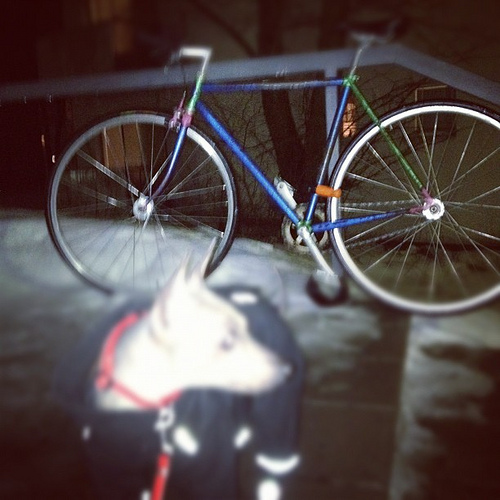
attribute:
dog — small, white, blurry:
[59, 236, 304, 499]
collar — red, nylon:
[93, 311, 184, 410]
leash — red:
[151, 409, 176, 500]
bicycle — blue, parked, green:
[44, 13, 500, 319]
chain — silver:
[279, 197, 445, 257]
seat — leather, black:
[338, 14, 409, 47]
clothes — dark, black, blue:
[52, 282, 300, 500]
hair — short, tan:
[95, 237, 295, 414]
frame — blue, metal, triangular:
[142, 43, 434, 236]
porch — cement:
[2, 295, 412, 499]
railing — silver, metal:
[1, 41, 500, 282]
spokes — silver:
[55, 123, 228, 283]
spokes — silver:
[338, 112, 499, 303]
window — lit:
[102, 118, 145, 167]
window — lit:
[108, 21, 133, 53]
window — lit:
[88, 1, 128, 23]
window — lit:
[341, 102, 357, 136]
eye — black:
[219, 329, 238, 352]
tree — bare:
[186, 1, 352, 248]